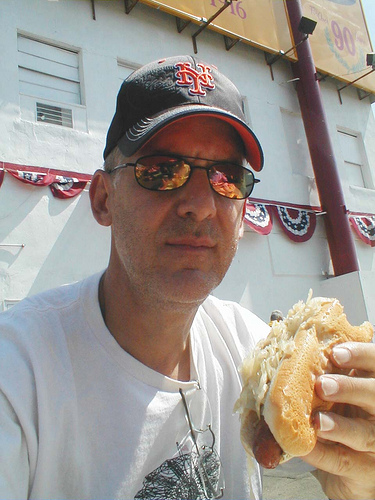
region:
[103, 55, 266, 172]
black and red cap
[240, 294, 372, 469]
hot dog bun in hand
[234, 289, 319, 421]
saurkraut on hot dog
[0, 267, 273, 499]
white cotton tee shirt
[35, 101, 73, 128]
air conditioner in wall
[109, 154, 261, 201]
sun glasses on face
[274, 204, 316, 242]
banner hanging on wall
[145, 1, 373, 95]
yellow billboard on wall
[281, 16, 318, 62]
light facing bill board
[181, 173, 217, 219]
The nose of the man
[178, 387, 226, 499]
Glasses on the man's shirt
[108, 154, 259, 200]
The man is wearing sunglasses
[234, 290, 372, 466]
The man is eating a hotdog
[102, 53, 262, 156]
The man is wearing a hat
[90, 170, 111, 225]
The right ear of the man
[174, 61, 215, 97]
A Mets logo on the hat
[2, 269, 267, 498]
The man is wearing a white shirt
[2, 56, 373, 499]
A man preapring to eat a hotdog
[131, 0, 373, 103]
A billboard above the man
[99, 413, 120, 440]
part fo a top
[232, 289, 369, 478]
Man holding hot dog in hand.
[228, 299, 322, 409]
Sauerkraut on top of hot dog.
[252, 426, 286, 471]
Hot dog between bun.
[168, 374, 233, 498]
Man's eyeglasses hooked on collard of t-shirt.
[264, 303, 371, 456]
Bottom part of hot dog bun.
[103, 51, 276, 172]
Man wearing baseball cap.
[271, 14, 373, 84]
Lights mounted below sign.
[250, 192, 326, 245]
Flags draped across back wall.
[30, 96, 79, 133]
Vent over a window.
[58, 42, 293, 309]
head of a person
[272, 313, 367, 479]
hand of a person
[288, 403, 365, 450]
finger of a person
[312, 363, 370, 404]
finger of a person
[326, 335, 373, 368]
finger of a person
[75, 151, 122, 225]
ear of a person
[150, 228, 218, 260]
mouth of a person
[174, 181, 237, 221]
nose of a person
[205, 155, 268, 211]
eye of a person